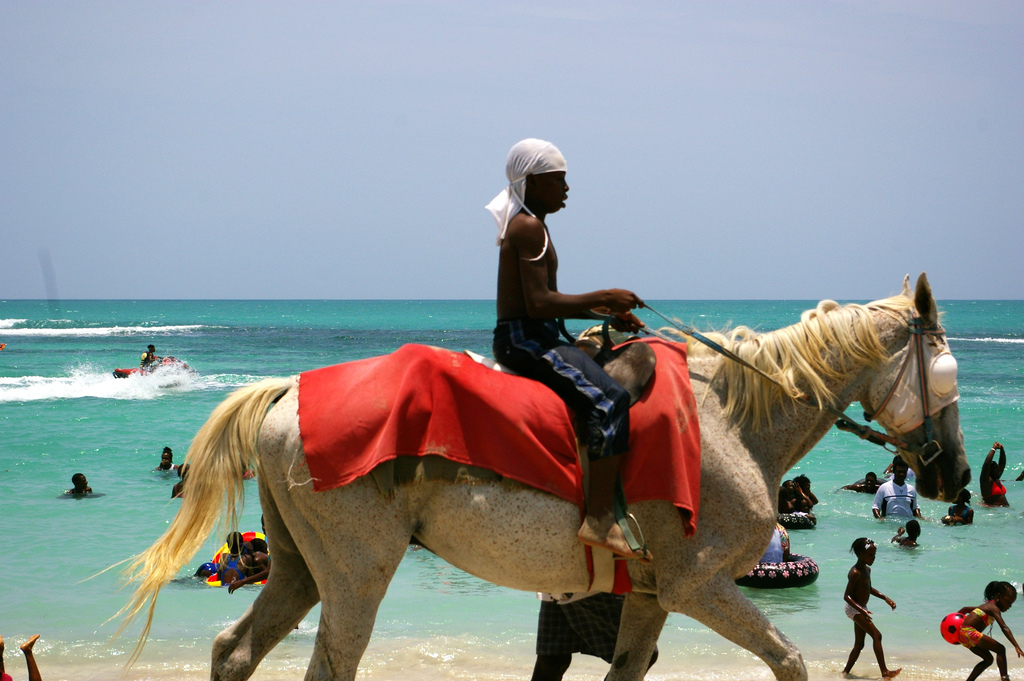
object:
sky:
[0, 0, 1021, 302]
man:
[482, 138, 655, 565]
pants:
[492, 317, 632, 462]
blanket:
[298, 336, 703, 540]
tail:
[79, 376, 300, 676]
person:
[941, 580, 1023, 681]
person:
[840, 537, 901, 679]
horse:
[80, 273, 964, 680]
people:
[68, 473, 92, 495]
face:
[865, 318, 971, 503]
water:
[0, 299, 1022, 658]